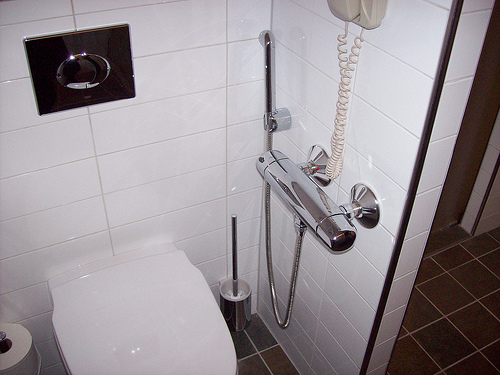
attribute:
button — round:
[53, 49, 113, 94]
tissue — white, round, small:
[0, 320, 37, 373]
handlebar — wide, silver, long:
[256, 155, 358, 257]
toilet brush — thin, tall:
[230, 218, 238, 296]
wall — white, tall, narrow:
[2, 1, 263, 372]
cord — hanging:
[325, 23, 361, 172]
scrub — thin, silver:
[215, 214, 253, 333]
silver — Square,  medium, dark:
[23, 25, 145, 116]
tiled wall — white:
[3, 1, 496, 372]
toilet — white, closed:
[44, 240, 238, 374]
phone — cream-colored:
[316, 3, 386, 185]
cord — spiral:
[317, 15, 376, 183]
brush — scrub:
[218, 214, 252, 333]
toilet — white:
[21, 239, 252, 374]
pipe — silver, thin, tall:
[250, 27, 309, 336]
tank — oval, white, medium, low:
[46, 247, 238, 374]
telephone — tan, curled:
[286, 20, 417, 164]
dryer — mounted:
[252, 145, 383, 255]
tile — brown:
[413, 269, 478, 324]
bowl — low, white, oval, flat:
[37, 230, 237, 371]